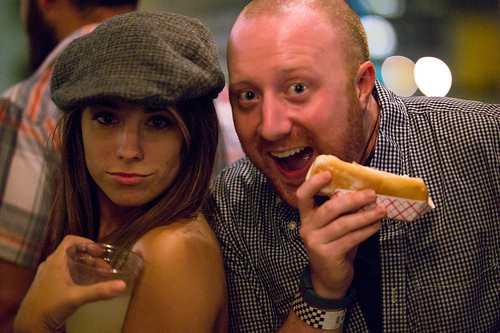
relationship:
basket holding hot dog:
[326, 188, 435, 222] [303, 158, 427, 200]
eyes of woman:
[79, 106, 176, 134] [11, 10, 226, 333]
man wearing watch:
[204, 0, 500, 333] [295, 267, 384, 312]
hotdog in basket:
[299, 153, 427, 203] [321, 183, 442, 224]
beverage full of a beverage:
[64, 240, 145, 333] [58, 288, 128, 328]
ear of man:
[352, 57, 376, 112] [204, 0, 500, 333]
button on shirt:
[288, 221, 297, 231] [209, 80, 451, 327]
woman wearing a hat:
[11, 10, 226, 333] [25, 10, 229, 110]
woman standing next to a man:
[11, 10, 226, 333] [204, 0, 500, 333]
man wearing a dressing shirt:
[204, 0, 500, 333] [201, 88, 484, 331]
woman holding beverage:
[11, 10, 226, 333] [56, 235, 152, 329]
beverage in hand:
[56, 235, 152, 329] [43, 238, 138, 331]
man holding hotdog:
[204, 0, 500, 333] [299, 151, 429, 195]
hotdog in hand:
[299, 151, 429, 195] [284, 164, 394, 298]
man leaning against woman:
[204, 0, 500, 333] [11, 10, 226, 333]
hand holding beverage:
[12, 231, 127, 327] [40, 240, 145, 330]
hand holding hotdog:
[293, 170, 387, 301] [299, 150, 438, 205]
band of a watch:
[283, 304, 350, 331] [284, 270, 320, 301]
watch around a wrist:
[284, 270, 320, 301] [294, 279, 354, 325]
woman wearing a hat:
[11, 10, 226, 333] [46, 10, 227, 111]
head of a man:
[217, 7, 379, 212] [204, 0, 500, 333]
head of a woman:
[49, 24, 210, 225] [11, 10, 226, 333]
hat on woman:
[42, 2, 233, 122] [11, 10, 226, 333]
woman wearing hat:
[11, 10, 226, 333] [41, 8, 237, 110]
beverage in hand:
[64, 240, 145, 333] [12, 231, 127, 327]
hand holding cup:
[12, 231, 127, 327] [55, 237, 149, 327]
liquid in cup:
[60, 284, 131, 331] [62, 231, 142, 327]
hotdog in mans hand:
[299, 153, 427, 203] [287, 161, 395, 291]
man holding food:
[219, 11, 482, 320] [298, 153, 433, 217]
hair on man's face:
[236, 84, 369, 191] [222, 7, 385, 199]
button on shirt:
[283, 217, 298, 238] [207, 78, 500, 333]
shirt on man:
[230, 116, 485, 318] [219, 11, 482, 320]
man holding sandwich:
[219, 11, 482, 320] [288, 155, 446, 218]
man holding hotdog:
[219, 11, 482, 320] [299, 153, 427, 203]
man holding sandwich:
[219, 11, 482, 320] [293, 150, 445, 213]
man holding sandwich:
[219, 11, 482, 320] [298, 152, 428, 227]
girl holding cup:
[8, 7, 226, 328] [53, 237, 152, 321]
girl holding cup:
[8, 7, 226, 328] [53, 237, 157, 330]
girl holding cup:
[8, 7, 226, 328] [55, 237, 149, 327]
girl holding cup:
[8, 7, 226, 328] [61, 233, 145, 323]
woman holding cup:
[11, 10, 226, 333] [55, 237, 149, 327]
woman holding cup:
[10, 10, 227, 323] [61, 233, 145, 323]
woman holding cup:
[10, 10, 227, 323] [54, 238, 143, 329]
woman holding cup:
[10, 10, 227, 323] [55, 237, 149, 327]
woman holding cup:
[10, 10, 227, 323] [60, 230, 151, 327]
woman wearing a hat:
[10, 10, 227, 323] [50, 4, 223, 107]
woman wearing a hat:
[10, 10, 227, 323] [40, 7, 222, 112]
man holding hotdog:
[204, 0, 500, 333] [299, 153, 427, 203]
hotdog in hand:
[299, 153, 427, 203] [297, 172, 387, 291]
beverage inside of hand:
[64, 240, 145, 333] [26, 236, 130, 329]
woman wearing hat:
[11, 10, 226, 333] [56, 40, 225, 100]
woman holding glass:
[11, 10, 226, 333] [69, 240, 137, 329]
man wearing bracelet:
[204, 0, 500, 333] [283, 280, 353, 331]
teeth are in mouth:
[261, 139, 311, 176] [264, 135, 313, 175]